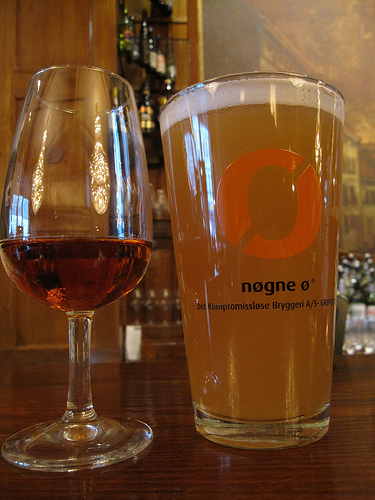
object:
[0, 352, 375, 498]
table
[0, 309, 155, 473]
leftbottom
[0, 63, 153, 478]
glass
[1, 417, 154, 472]
bottom